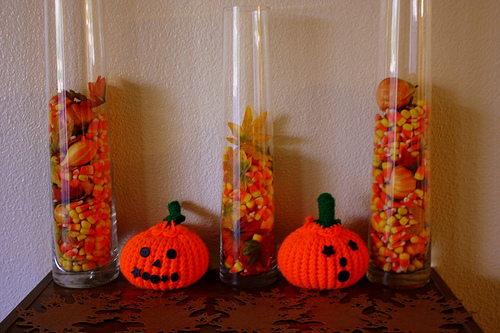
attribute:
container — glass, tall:
[42, 1, 127, 290]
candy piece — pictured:
[372, 69, 416, 107]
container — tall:
[371, 0, 433, 287]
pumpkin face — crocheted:
[117, 201, 210, 289]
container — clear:
[375, 7, 431, 284]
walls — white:
[110, 8, 375, 121]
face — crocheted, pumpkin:
[308, 230, 358, 285]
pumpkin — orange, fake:
[117, 195, 213, 294]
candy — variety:
[221, 112, 277, 284]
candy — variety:
[368, 72, 436, 274]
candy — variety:
[48, 82, 116, 273]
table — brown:
[2, 260, 484, 331]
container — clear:
[36, 2, 131, 293]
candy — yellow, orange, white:
[385, 213, 400, 225]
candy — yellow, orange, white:
[389, 241, 419, 266]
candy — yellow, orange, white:
[380, 156, 391, 183]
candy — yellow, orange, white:
[246, 181, 260, 197]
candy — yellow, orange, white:
[255, 205, 267, 224]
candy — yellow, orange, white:
[227, 259, 244, 274]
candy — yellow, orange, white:
[90, 163, 107, 179]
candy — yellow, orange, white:
[87, 116, 104, 136]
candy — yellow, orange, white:
[76, 203, 92, 223]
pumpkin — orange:
[117, 201, 212, 287]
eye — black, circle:
[138, 239, 149, 256]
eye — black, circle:
[161, 240, 175, 259]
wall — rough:
[4, 2, 499, 321]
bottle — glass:
[365, 2, 440, 294]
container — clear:
[217, 8, 279, 280]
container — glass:
[210, 12, 282, 279]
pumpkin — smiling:
[112, 200, 215, 280]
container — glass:
[346, 27, 466, 274]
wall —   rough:
[320, 67, 362, 124]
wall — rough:
[286, 22, 363, 150]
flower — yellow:
[229, 107, 268, 157]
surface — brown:
[135, 300, 269, 326]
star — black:
[130, 265, 141, 278]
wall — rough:
[428, 1, 497, 330]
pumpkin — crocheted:
[125, 200, 207, 291]